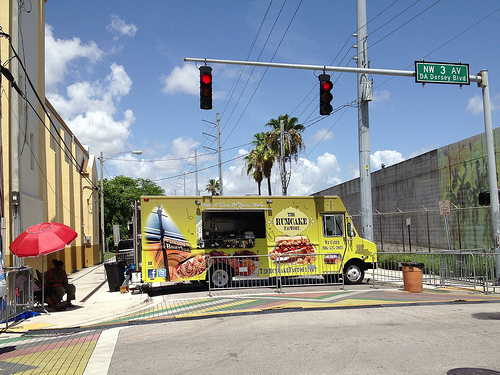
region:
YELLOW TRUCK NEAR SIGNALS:
[121, 176, 370, 291]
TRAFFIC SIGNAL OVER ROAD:
[193, 65, 214, 110]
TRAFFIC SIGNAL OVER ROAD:
[314, 73, 335, 124]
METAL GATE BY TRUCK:
[217, 256, 340, 284]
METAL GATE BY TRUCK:
[371, 256, 477, 280]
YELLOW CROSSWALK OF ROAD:
[0, 326, 105, 371]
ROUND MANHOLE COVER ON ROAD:
[439, 360, 499, 374]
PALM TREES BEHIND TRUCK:
[253, 111, 293, 173]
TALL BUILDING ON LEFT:
[0, 119, 97, 271]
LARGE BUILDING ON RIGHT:
[380, 164, 492, 241]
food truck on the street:
[84, 165, 383, 287]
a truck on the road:
[85, 140, 457, 361]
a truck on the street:
[139, 164, 303, 349]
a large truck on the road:
[129, 146, 331, 293]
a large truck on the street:
[92, 134, 410, 328]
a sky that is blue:
[96, 108, 194, 158]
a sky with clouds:
[92, 113, 244, 173]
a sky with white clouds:
[71, 119, 257, 196]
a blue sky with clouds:
[85, 111, 271, 176]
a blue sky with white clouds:
[99, 118, 225, 177]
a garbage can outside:
[416, 246, 446, 306]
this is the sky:
[96, 5, 146, 30]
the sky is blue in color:
[171, 19, 209, 35]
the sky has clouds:
[82, 83, 148, 129]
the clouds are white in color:
[94, 121, 114, 138]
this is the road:
[252, 329, 291, 354]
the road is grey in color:
[265, 322, 317, 367]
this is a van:
[132, 178, 362, 298]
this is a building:
[50, 140, 96, 202]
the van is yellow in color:
[180, 209, 191, 218]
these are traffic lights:
[198, 64, 332, 126]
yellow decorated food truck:
[137, 195, 376, 283]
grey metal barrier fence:
[204, 254, 499, 289]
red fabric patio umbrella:
[13, 222, 79, 258]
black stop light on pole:
[198, 66, 212, 111]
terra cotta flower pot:
[401, 267, 423, 292]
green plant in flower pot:
[401, 255, 424, 271]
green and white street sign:
[415, 64, 469, 86]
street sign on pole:
[416, 62, 471, 86]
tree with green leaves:
[98, 174, 165, 236]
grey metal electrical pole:
[357, 0, 374, 250]